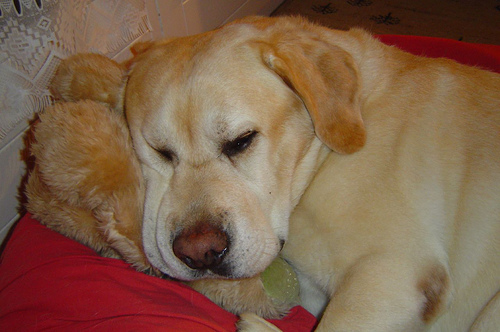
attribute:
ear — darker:
[255, 24, 375, 162]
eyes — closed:
[144, 120, 268, 165]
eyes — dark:
[147, 122, 268, 169]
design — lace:
[6, 0, 59, 76]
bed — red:
[11, 207, 246, 329]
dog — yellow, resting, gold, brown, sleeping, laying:
[119, 11, 495, 329]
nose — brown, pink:
[168, 227, 238, 277]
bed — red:
[8, 219, 191, 328]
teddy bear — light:
[14, 44, 288, 329]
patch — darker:
[424, 259, 454, 329]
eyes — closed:
[157, 126, 267, 166]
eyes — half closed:
[133, 123, 260, 174]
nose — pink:
[174, 223, 233, 278]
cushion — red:
[13, 219, 162, 328]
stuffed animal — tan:
[13, 46, 153, 262]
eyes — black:
[140, 120, 266, 170]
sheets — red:
[1, 209, 319, 329]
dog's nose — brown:
[170, 219, 229, 270]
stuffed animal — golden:
[14, 50, 164, 281]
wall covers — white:
[3, 10, 190, 170]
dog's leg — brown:
[306, 190, 462, 330]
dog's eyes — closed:
[149, 120, 269, 167]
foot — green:
[261, 250, 301, 320]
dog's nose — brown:
[171, 224, 231, 267]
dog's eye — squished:
[142, 134, 180, 172]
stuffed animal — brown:
[21, 50, 308, 322]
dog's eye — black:
[218, 127, 259, 162]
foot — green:
[261, 252, 297, 311]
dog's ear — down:
[260, 34, 371, 159]